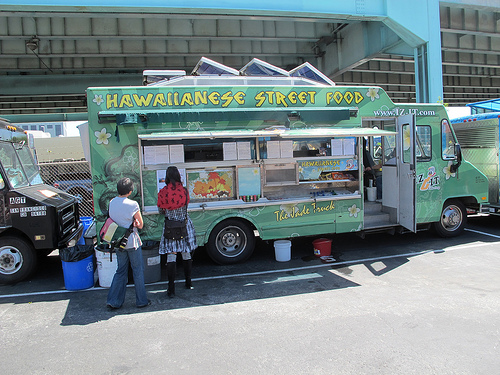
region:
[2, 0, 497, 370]
This is a street scene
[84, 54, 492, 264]
A food truck is parked on the street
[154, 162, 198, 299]
A woman is beside the truck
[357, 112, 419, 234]
The tricks door is open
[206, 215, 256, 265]
The truck's rear wheel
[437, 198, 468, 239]
The truck's front wheel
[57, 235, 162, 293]
Garbage cans are beside the truck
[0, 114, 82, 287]
Another truck is parked behind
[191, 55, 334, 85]
Solar panels are on top the truck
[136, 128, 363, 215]
The truck's service window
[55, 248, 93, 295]
Blue trash can on the side.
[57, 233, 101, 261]
Black trash bag in can.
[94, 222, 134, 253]
Bag around girls back.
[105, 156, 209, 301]
People next to food truck.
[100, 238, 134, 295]
White trash can on the ground.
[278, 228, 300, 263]
White bucket under truck.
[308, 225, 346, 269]
Red bucket under truck.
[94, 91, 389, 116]
Yellow letters on side of truck.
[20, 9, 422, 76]
Building behind the bus.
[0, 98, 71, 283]
Brown food truck behind trash cans.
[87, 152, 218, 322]
Two people standing on the street.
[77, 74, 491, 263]
A green food truck.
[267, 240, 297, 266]
A white bucket on the ground.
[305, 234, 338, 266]
A red bucket on the ground.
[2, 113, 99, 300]
Blue recycling can in front of a black van.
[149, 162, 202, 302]
A female wearing a skirt.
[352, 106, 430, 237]
An open door on a food truck.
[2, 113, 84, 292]
A black van.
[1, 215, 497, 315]
White stripe painted on a parking lot.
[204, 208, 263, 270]
Tire on a food truck.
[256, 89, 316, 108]
the word street on the van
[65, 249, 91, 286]
a blue trash can garbage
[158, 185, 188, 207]
this is red with black dots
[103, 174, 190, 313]
two people buying somethig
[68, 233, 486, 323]
the shadow of the van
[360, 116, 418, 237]
the door is open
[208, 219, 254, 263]
one tire of the van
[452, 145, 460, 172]
the rearview mirror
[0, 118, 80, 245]
the front view of one van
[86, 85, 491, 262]
the vehicle is green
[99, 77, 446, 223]
This is a truck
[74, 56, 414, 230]
This is a food truck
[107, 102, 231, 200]
The truck is green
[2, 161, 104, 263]
The truck is black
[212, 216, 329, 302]
This is a wheel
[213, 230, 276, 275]
This is a tire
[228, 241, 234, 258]
This is a wheel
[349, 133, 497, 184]
The window is small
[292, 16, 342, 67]
This is a bridge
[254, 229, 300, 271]
This is a bucket